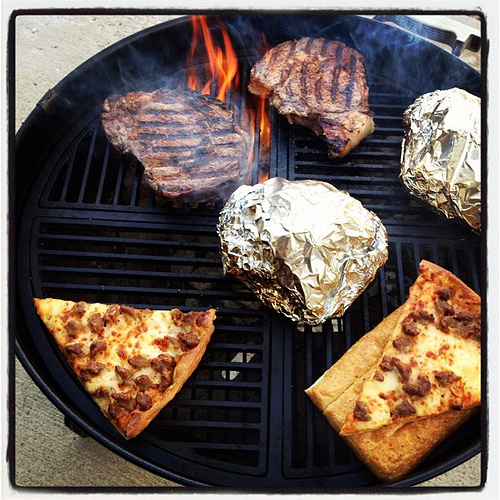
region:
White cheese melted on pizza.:
[96, 374, 115, 389]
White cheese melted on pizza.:
[146, 313, 161, 333]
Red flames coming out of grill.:
[177, 41, 274, 110]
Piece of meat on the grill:
[94, 83, 255, 183]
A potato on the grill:
[221, 174, 386, 325]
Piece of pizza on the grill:
[26, 280, 211, 449]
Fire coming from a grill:
[172, 29, 244, 94]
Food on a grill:
[36, 20, 483, 457]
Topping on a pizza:
[88, 339, 105, 354]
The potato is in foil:
[226, 177, 376, 322]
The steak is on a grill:
[108, 86, 251, 183]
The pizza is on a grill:
[30, 285, 223, 451]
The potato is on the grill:
[228, 175, 377, 327]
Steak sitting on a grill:
[111, 80, 243, 202]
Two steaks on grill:
[93, 31, 379, 193]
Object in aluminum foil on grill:
[216, 182, 384, 331]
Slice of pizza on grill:
[33, 278, 215, 435]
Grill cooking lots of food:
[16, 14, 480, 484]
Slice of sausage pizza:
[387, 267, 487, 406]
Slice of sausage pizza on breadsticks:
[303, 295, 471, 477]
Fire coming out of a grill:
[153, 25, 250, 92]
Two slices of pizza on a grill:
[43, 295, 484, 465]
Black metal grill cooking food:
[21, 29, 470, 485]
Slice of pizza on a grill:
[32, 294, 215, 438]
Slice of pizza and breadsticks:
[304, 257, 481, 481]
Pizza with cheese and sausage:
[30, 295, 213, 440]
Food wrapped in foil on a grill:
[215, 173, 391, 326]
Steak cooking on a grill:
[100, 87, 250, 210]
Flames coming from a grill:
[183, 8, 273, 190]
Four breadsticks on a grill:
[302, 296, 479, 478]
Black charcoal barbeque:
[15, 11, 481, 484]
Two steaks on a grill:
[98, 35, 374, 209]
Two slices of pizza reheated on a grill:
[30, 255, 480, 442]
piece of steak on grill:
[123, 84, 248, 194]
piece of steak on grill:
[263, 24, 353, 121]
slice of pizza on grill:
[19, 288, 226, 400]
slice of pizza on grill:
[333, 276, 495, 467]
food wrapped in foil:
[230, 199, 380, 315]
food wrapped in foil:
[396, 85, 498, 207]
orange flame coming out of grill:
[177, 14, 265, 130]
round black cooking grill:
[33, 51, 498, 444]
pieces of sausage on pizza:
[398, 324, 421, 340]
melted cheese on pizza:
[80, 315, 192, 372]